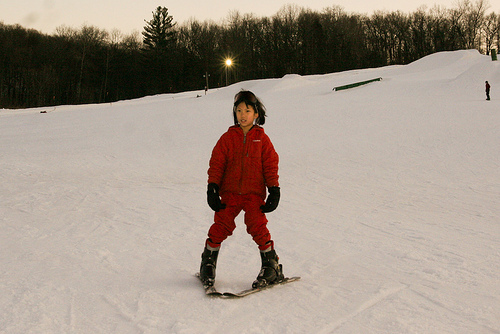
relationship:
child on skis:
[149, 71, 317, 331] [175, 260, 305, 309]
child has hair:
[195, 88, 301, 298] [209, 85, 279, 114]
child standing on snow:
[195, 88, 301, 298] [6, 60, 496, 331]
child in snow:
[195, 88, 301, 298] [6, 60, 496, 331]